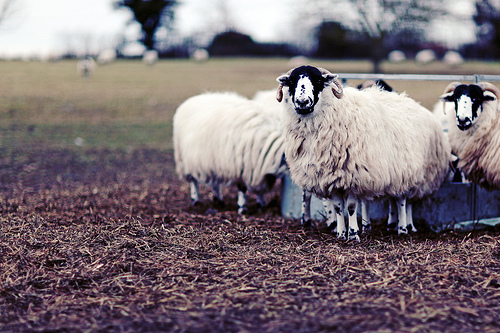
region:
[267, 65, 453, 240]
black and white sheep in field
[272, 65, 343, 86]
two sheep ears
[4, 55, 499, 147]
blurred green grass in field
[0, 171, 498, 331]
brown straw in foreground of field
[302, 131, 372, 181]
long fur on sheep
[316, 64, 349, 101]
horns on top of sheep head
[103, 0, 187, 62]
tall tree in field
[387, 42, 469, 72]
blurred sheep in field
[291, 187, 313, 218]
black spots on white legs of sheep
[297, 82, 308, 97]
black spots on nose of sheep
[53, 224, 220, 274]
withered bush on the ground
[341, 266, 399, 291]
small section of twig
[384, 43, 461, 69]
white bundles in the back ground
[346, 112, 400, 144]
large patch of wool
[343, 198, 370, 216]
black spot on sheep's knee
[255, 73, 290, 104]
brown sheep's horn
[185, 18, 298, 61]
large building behind the sheep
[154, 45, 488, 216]
several sheep in the yard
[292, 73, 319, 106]
splash of white on face of sheep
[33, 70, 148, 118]
green in the yard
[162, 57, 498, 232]
a group of sheep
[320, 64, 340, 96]
a horn on a sheep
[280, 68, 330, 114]
the face of a sheep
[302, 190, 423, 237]
the legs of a sheep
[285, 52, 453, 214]
a sheep with white and black wool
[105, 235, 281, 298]
straw on the dirt ground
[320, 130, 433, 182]
long wool on a sheep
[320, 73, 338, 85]
the left ear of a sheep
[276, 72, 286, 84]
the right ear of a sheep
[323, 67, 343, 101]
a horn that is curled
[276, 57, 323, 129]
sheep's face is black and white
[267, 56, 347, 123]
a black and white face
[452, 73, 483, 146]
a black and white face